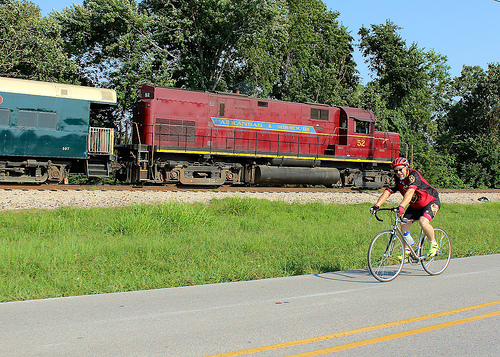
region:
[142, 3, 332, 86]
trees next to train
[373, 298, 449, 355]
yellow lines on the road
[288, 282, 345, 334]
gray ground under bike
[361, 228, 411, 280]
wheel on the bike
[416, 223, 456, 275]
back tire of the bike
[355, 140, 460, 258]
person the bike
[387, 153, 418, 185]
helmet on the man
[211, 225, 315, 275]
grass next to man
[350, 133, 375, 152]
number on the train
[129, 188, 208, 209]
rocks next to train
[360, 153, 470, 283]
A man riding the bike.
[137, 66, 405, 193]
A train engine leading the train.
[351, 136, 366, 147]
The number 52 on the train.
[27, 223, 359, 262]
Grass between the road and tracks.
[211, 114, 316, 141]
A blue banner on the train.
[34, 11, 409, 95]
Trees lining the tracks.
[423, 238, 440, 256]
Green shoes on the man.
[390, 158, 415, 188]
A man wearing a helmet.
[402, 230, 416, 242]
A water bottle attached to the bike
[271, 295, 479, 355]
Yellow lines in the road.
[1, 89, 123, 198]
Two tone blue train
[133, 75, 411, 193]
Dusty Red Train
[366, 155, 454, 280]
Man Riding a bicycle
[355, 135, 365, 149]
Yellow 52 logo on the train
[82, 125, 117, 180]
Stairs leading to the train compartment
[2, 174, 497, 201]
Rusted Metal Train Tracks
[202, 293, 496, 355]
Two yellow line on the street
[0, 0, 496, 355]
Train tracks next to the road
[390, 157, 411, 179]
Bright Red Bikers Helmet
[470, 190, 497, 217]
Debris on the side of the train track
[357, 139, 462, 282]
a man riding a bike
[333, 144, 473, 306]
a man riding a bike on a street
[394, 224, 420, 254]
a plastic water bottle attached to a bike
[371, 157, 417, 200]
a man wearing sunglasses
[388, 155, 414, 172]
a man wearing a red and black helmet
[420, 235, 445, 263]
a man wearing green shoes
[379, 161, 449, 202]
a man wearing a black and red shirt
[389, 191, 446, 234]
a man wearing black and red shorts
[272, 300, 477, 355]
yellow lines painted on a road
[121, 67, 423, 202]
a red train engine car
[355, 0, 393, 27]
white clouds in blue sky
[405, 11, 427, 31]
white clouds in blue sky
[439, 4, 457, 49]
white clouds in blue sky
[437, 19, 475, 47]
white clouds in blue sky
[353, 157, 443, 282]
cyclist on road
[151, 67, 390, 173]
red train engine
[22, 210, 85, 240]
short green and brown grass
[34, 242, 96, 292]
short green and brown grass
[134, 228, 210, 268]
short green and brown grass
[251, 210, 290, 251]
short green and brown grass